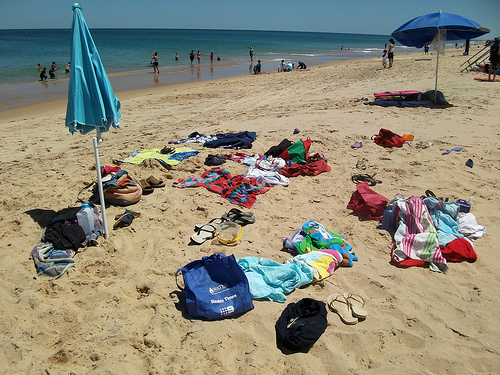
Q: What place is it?
A: It is a beach.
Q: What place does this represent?
A: It represents the beach.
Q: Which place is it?
A: It is a beach.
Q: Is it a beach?
A: Yes, it is a beach.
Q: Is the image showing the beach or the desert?
A: It is showing the beach.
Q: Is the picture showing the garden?
A: No, the picture is showing the beach.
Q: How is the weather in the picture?
A: It is clear.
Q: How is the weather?
A: It is clear.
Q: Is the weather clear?
A: Yes, it is clear.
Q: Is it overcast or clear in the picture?
A: It is clear.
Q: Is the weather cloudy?
A: No, it is clear.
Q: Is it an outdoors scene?
A: Yes, it is outdoors.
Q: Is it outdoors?
A: Yes, it is outdoors.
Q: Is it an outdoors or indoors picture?
A: It is outdoors.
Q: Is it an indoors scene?
A: No, it is outdoors.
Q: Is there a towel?
A: Yes, there is a towel.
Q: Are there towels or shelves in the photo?
A: Yes, there is a towel.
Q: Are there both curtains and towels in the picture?
A: No, there is a towel but no curtains.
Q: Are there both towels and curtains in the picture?
A: No, there is a towel but no curtains.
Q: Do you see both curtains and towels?
A: No, there is a towel but no curtains.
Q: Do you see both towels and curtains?
A: No, there is a towel but no curtains.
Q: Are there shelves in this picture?
A: No, there are no shelves.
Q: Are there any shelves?
A: No, there are no shelves.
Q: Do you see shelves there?
A: No, there are no shelves.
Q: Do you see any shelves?
A: No, there are no shelves.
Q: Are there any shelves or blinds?
A: No, there are no shelves or blinds.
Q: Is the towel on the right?
A: Yes, the towel is on the right of the image.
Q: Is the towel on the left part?
A: No, the towel is on the right of the image.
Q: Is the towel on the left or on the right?
A: The towel is on the right of the image.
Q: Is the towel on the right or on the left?
A: The towel is on the right of the image.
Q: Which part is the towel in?
A: The towel is on the right of the image.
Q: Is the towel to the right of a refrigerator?
A: No, the towel is to the right of the bag.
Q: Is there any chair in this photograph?
A: Yes, there is a chair.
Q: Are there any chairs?
A: Yes, there is a chair.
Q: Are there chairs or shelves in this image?
A: Yes, there is a chair.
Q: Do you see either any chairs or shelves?
A: Yes, there is a chair.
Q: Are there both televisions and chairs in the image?
A: No, there is a chair but no televisions.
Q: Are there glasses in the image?
A: No, there are no glasses.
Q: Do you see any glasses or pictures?
A: No, there are no glasses or pictures.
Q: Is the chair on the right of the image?
A: Yes, the chair is on the right of the image.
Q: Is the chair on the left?
A: No, the chair is on the right of the image.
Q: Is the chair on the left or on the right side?
A: The chair is on the right of the image.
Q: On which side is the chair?
A: The chair is on the right of the image.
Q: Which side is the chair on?
A: The chair is on the right of the image.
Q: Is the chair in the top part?
A: Yes, the chair is in the top of the image.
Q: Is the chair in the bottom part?
A: No, the chair is in the top of the image.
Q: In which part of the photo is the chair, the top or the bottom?
A: The chair is in the top of the image.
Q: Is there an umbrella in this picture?
A: Yes, there is an umbrella.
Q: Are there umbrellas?
A: Yes, there is an umbrella.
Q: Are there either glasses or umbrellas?
A: Yes, there is an umbrella.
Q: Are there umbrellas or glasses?
A: Yes, there is an umbrella.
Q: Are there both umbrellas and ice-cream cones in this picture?
A: No, there is an umbrella but no ice-cream cones.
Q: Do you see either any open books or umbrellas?
A: Yes, there is an open umbrella.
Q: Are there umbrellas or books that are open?
A: Yes, the umbrella is open.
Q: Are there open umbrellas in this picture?
A: Yes, there is an open umbrella.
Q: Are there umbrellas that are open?
A: Yes, there is an umbrella that is open.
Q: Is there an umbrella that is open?
A: Yes, there is an umbrella that is open.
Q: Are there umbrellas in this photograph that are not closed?
A: Yes, there is a open umbrella.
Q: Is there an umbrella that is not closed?
A: Yes, there is a open umbrella.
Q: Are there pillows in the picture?
A: No, there are no pillows.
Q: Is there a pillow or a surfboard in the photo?
A: No, there are no pillows or surfboards.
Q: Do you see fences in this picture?
A: No, there are no fences.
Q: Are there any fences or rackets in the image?
A: No, there are no fences or rackets.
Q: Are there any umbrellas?
A: Yes, there is an umbrella.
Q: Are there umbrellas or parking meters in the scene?
A: Yes, there is an umbrella.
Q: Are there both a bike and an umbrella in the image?
A: No, there is an umbrella but no bikes.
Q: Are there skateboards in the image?
A: No, there are no skateboards.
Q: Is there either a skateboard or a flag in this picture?
A: No, there are no skateboards or flags.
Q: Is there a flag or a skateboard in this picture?
A: No, there are no skateboards or flags.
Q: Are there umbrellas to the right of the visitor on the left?
A: Yes, there is an umbrella to the right of the visitor.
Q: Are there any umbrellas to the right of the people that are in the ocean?
A: Yes, there is an umbrella to the right of the people.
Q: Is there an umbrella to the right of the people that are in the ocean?
A: Yes, there is an umbrella to the right of the people.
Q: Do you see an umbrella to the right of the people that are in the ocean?
A: Yes, there is an umbrella to the right of the people.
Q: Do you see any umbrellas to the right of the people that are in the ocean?
A: Yes, there is an umbrella to the right of the people.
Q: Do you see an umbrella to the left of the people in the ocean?
A: No, the umbrella is to the right of the people.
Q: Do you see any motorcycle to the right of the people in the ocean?
A: No, there is an umbrella to the right of the people.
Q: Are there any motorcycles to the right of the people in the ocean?
A: No, there is an umbrella to the right of the people.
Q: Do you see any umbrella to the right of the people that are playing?
A: Yes, there is an umbrella to the right of the people.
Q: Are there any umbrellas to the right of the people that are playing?
A: Yes, there is an umbrella to the right of the people.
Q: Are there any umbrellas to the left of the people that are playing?
A: No, the umbrella is to the right of the people.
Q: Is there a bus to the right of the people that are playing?
A: No, there is an umbrella to the right of the people.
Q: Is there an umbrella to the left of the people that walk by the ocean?
A: Yes, there is an umbrella to the left of the people.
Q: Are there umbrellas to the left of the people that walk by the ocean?
A: Yes, there is an umbrella to the left of the people.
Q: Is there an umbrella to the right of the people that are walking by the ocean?
A: No, the umbrella is to the left of the people.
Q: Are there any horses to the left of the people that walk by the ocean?
A: No, there is an umbrella to the left of the people.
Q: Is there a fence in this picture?
A: No, there are no fences.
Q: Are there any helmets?
A: No, there are no helmets.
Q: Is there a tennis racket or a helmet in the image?
A: No, there are no helmets or rackets.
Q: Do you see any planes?
A: No, there are no planes.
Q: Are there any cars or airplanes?
A: No, there are no airplanes or cars.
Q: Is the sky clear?
A: Yes, the sky is clear.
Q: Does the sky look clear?
A: Yes, the sky is clear.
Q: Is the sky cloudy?
A: No, the sky is clear.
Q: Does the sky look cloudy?
A: No, the sky is clear.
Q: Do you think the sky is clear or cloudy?
A: The sky is clear.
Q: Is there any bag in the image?
A: Yes, there is a bag.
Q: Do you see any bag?
A: Yes, there is a bag.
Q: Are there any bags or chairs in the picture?
A: Yes, there is a bag.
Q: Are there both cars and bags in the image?
A: No, there is a bag but no cars.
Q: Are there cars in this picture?
A: No, there are no cars.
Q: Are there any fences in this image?
A: No, there are no fences.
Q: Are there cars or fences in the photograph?
A: No, there are no fences or cars.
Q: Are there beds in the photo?
A: No, there are no beds.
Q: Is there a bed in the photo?
A: No, there are no beds.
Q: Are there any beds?
A: No, there are no beds.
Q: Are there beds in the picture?
A: No, there are no beds.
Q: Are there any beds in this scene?
A: No, there are no beds.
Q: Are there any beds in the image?
A: No, there are no beds.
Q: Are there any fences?
A: No, there are no fences.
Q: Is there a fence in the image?
A: No, there are no fences.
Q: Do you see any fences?
A: No, there are no fences.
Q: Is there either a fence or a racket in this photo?
A: No, there are no fences or rackets.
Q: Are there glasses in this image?
A: No, there are no glasses.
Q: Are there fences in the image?
A: No, there are no fences.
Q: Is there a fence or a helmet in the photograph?
A: No, there are no fences or helmets.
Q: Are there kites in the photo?
A: No, there are no kites.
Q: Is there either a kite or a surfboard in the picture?
A: No, there are no kites or surfboards.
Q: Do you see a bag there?
A: Yes, there is a bag.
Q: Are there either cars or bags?
A: Yes, there is a bag.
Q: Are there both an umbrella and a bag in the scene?
A: Yes, there are both a bag and an umbrella.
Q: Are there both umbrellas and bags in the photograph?
A: Yes, there are both a bag and an umbrella.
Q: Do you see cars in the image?
A: No, there are no cars.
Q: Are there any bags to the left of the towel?
A: Yes, there is a bag to the left of the towel.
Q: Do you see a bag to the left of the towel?
A: Yes, there is a bag to the left of the towel.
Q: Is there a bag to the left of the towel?
A: Yes, there is a bag to the left of the towel.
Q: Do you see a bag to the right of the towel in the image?
A: No, the bag is to the left of the towel.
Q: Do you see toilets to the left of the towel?
A: No, there is a bag to the left of the towel.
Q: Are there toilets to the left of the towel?
A: No, there is a bag to the left of the towel.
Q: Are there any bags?
A: Yes, there is a bag.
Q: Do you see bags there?
A: Yes, there is a bag.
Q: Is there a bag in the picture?
A: Yes, there is a bag.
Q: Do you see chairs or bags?
A: Yes, there is a bag.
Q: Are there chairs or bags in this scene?
A: Yes, there is a bag.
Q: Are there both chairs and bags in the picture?
A: Yes, there are both a bag and a chair.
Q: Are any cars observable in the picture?
A: No, there are no cars.